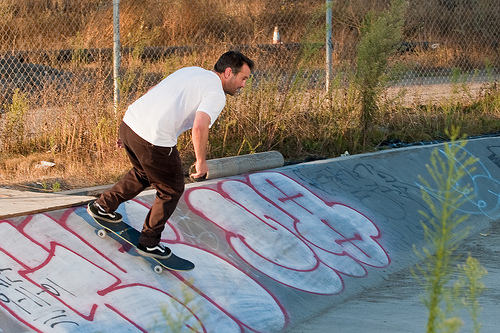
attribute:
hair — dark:
[214, 42, 251, 85]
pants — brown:
[95, 117, 185, 247]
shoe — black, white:
[137, 237, 170, 257]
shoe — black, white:
[84, 199, 124, 221]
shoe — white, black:
[142, 238, 170, 258]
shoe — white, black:
[87, 200, 123, 221]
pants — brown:
[99, 120, 184, 239]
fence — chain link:
[1, 1, 498, 139]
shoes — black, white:
[84, 189, 178, 266]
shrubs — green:
[296, 53, 493, 125]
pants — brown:
[93, 121, 186, 241]